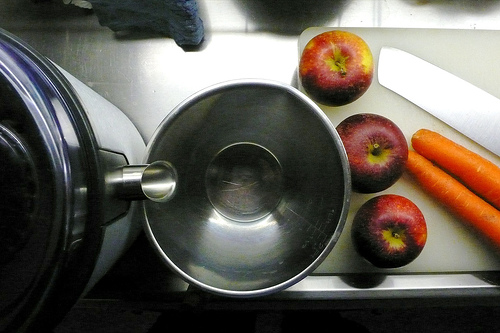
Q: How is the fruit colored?
A: Red and orange.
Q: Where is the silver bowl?
A: Next to the food.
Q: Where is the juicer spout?
A: Above the bowl.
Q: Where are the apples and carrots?
A: Cutting board.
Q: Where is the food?
A: Near juicer.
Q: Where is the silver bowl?
A: Near the food.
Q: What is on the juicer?
A: Silver bowl.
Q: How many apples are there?
A: Three.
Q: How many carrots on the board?
A: Two.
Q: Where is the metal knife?
A: On the cutting board.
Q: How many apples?
A: 3.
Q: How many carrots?
A: 2.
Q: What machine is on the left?
A: A juicer.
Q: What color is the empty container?
A: Silver.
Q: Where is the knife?
A: On the cutting board.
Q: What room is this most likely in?
A: A kitchen.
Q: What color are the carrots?
A: Orange.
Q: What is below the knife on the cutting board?
A: Carrots.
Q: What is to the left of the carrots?
A: Apples.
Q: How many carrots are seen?
A: Two.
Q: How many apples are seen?
A: Three.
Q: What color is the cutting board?
A: White.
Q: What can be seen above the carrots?
A: A knife.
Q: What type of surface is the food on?
A: Stainless steel.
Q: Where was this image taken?
A: Kitchen.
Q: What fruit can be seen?
A: Apples.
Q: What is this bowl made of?
A: Silver.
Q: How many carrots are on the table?
A: 2.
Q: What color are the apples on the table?
A: Red and yellow.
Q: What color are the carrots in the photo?
A: Orange.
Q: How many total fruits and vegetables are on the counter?
A: 5.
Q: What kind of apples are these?
A: Gala.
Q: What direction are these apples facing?
A: Overhead.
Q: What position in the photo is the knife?
A: Top right corner.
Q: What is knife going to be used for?
A: Cutting fruits and vegetables.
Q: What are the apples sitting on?
A: Cutting board.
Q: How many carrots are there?
A: Two.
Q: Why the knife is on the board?
A: To chopped carrots.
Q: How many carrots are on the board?
A: Two.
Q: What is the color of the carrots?
A: Orange.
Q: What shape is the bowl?
A: Circle.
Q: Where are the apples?
A: On top of cutting board.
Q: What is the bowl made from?
A: Steel.